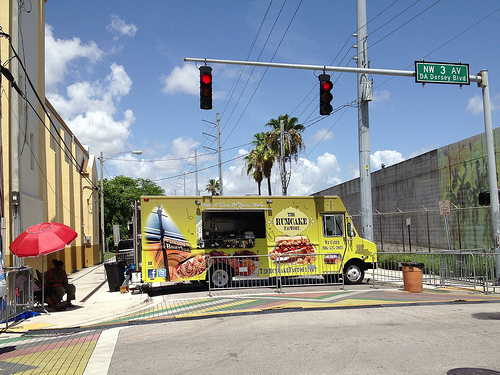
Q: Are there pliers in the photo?
A: No, there are no pliers.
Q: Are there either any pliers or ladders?
A: No, there are no pliers or ladders.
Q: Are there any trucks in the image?
A: Yes, there is a truck.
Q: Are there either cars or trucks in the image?
A: Yes, there is a truck.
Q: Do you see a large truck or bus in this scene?
A: Yes, there is a large truck.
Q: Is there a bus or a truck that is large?
A: Yes, the truck is large.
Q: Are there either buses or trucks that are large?
A: Yes, the truck is large.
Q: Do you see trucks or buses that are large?
A: Yes, the truck is large.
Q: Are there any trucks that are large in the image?
A: Yes, there is a large truck.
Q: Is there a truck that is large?
A: Yes, there is a truck that is large.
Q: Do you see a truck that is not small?
A: Yes, there is a large truck.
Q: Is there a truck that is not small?
A: Yes, there is a large truck.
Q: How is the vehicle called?
A: The vehicle is a truck.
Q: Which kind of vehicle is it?
A: The vehicle is a truck.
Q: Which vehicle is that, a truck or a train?
A: That is a truck.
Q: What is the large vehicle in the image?
A: The vehicle is a truck.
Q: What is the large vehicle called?
A: The vehicle is a truck.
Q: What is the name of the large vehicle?
A: The vehicle is a truck.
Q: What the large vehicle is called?
A: The vehicle is a truck.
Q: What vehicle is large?
A: The vehicle is a truck.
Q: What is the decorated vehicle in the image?
A: The vehicle is a truck.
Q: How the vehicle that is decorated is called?
A: The vehicle is a truck.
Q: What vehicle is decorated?
A: The vehicle is a truck.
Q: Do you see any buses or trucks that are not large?
A: No, there is a truck but it is large.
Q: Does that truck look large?
A: Yes, the truck is large.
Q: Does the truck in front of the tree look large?
A: Yes, the truck is large.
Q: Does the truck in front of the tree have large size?
A: Yes, the truck is large.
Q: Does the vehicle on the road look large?
A: Yes, the truck is large.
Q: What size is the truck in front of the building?
A: The truck is large.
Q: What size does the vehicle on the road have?
A: The truck has large size.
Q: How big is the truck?
A: The truck is large.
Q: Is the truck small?
A: No, the truck is large.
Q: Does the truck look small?
A: No, the truck is large.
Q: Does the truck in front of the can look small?
A: No, the truck is large.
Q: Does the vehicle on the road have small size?
A: No, the truck is large.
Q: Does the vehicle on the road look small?
A: No, the truck is large.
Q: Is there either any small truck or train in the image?
A: No, there is a truck but it is large.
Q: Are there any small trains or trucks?
A: No, there is a truck but it is large.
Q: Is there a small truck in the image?
A: No, there is a truck but it is large.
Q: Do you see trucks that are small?
A: No, there is a truck but it is large.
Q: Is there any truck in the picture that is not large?
A: No, there is a truck but it is large.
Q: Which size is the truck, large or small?
A: The truck is large.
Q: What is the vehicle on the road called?
A: The vehicle is a truck.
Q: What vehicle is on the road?
A: The vehicle is a truck.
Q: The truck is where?
A: The truck is on the road.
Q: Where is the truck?
A: The truck is on the road.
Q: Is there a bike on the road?
A: No, there is a truck on the road.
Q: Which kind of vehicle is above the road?
A: The vehicle is a truck.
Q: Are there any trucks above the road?
A: Yes, there is a truck above the road.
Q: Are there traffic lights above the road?
A: No, there is a truck above the road.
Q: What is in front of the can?
A: The truck is in front of the can.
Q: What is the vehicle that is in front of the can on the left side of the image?
A: The vehicle is a truck.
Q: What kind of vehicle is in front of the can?
A: The vehicle is a truck.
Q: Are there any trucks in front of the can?
A: Yes, there is a truck in front of the can.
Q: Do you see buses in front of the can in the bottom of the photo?
A: No, there is a truck in front of the can.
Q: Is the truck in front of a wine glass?
A: No, the truck is in front of the can.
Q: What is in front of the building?
A: The truck is in front of the building.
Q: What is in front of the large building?
A: The truck is in front of the building.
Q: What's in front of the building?
A: The truck is in front of the building.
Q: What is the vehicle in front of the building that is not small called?
A: The vehicle is a truck.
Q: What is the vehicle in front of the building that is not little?
A: The vehicle is a truck.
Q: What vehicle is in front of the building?
A: The vehicle is a truck.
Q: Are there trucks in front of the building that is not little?
A: Yes, there is a truck in front of the building.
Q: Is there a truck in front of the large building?
A: Yes, there is a truck in front of the building.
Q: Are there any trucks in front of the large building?
A: Yes, there is a truck in front of the building.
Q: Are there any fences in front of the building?
A: No, there is a truck in front of the building.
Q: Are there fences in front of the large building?
A: No, there is a truck in front of the building.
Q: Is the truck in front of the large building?
A: Yes, the truck is in front of the building.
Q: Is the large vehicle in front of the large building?
A: Yes, the truck is in front of the building.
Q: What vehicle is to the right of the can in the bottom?
A: The vehicle is a truck.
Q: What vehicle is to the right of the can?
A: The vehicle is a truck.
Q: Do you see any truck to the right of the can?
A: Yes, there is a truck to the right of the can.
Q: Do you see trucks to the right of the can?
A: Yes, there is a truck to the right of the can.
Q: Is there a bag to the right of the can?
A: No, there is a truck to the right of the can.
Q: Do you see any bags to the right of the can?
A: No, there is a truck to the right of the can.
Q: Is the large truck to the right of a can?
A: Yes, the truck is to the right of a can.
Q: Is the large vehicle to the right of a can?
A: Yes, the truck is to the right of a can.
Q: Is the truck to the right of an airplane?
A: No, the truck is to the right of a can.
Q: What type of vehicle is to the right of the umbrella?
A: The vehicle is a truck.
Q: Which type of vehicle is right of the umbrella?
A: The vehicle is a truck.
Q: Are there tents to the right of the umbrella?
A: No, there is a truck to the right of the umbrella.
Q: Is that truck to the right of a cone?
A: No, the truck is to the right of the umbrella.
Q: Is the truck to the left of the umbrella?
A: No, the truck is to the right of the umbrella.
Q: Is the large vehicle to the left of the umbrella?
A: No, the truck is to the right of the umbrella.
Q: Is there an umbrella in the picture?
A: Yes, there is an umbrella.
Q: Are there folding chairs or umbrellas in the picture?
A: Yes, there is an umbrella.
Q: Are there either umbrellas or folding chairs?
A: Yes, there is an umbrella.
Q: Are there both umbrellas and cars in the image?
A: No, there is an umbrella but no cars.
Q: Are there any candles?
A: No, there are no candles.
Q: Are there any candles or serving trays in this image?
A: No, there are no candles or serving trays.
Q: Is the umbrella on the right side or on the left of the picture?
A: The umbrella is on the left of the image.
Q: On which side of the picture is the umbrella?
A: The umbrella is on the left of the image.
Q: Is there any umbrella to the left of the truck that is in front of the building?
A: Yes, there is an umbrella to the left of the truck.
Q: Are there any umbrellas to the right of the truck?
A: No, the umbrella is to the left of the truck.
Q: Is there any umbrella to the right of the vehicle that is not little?
A: No, the umbrella is to the left of the truck.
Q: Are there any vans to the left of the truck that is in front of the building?
A: No, there is an umbrella to the left of the truck.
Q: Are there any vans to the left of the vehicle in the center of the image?
A: No, there is an umbrella to the left of the truck.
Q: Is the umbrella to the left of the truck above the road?
A: Yes, the umbrella is to the left of the truck.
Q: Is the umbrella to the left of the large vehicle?
A: Yes, the umbrella is to the left of the truck.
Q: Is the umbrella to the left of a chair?
A: No, the umbrella is to the left of the truck.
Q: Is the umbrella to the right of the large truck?
A: No, the umbrella is to the left of the truck.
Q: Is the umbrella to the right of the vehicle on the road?
A: No, the umbrella is to the left of the truck.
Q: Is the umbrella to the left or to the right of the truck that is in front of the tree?
A: The umbrella is to the left of the truck.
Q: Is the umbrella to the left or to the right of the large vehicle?
A: The umbrella is to the left of the truck.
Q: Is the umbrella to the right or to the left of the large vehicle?
A: The umbrella is to the left of the truck.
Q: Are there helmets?
A: No, there are no helmets.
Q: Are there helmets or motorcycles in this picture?
A: No, there are no helmets or motorcycles.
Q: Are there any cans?
A: Yes, there is a can.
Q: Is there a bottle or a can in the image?
A: Yes, there is a can.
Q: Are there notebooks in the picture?
A: No, there are no notebooks.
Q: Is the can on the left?
A: Yes, the can is on the left of the image.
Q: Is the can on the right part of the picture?
A: No, the can is on the left of the image.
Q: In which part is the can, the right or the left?
A: The can is on the left of the image.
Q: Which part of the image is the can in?
A: The can is on the left of the image.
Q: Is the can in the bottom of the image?
A: Yes, the can is in the bottom of the image.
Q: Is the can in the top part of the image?
A: No, the can is in the bottom of the image.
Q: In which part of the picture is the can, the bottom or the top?
A: The can is in the bottom of the image.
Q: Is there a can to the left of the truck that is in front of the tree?
A: Yes, there is a can to the left of the truck.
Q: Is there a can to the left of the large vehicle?
A: Yes, there is a can to the left of the truck.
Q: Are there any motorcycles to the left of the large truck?
A: No, there is a can to the left of the truck.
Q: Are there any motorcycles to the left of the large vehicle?
A: No, there is a can to the left of the truck.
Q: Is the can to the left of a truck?
A: Yes, the can is to the left of a truck.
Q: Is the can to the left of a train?
A: No, the can is to the left of a truck.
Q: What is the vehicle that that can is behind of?
A: The vehicle is a truck.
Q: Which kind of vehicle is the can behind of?
A: The can is behind the truck.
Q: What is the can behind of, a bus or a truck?
A: The can is behind a truck.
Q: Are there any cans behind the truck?
A: Yes, there is a can behind the truck.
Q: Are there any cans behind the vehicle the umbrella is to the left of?
A: Yes, there is a can behind the truck.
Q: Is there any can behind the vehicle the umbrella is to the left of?
A: Yes, there is a can behind the truck.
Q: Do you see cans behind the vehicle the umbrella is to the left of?
A: Yes, there is a can behind the truck.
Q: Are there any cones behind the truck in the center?
A: No, there is a can behind the truck.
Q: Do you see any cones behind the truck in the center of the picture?
A: No, there is a can behind the truck.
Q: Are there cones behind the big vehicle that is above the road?
A: No, there is a can behind the truck.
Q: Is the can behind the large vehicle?
A: Yes, the can is behind the truck.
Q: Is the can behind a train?
A: No, the can is behind the truck.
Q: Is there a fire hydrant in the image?
A: No, there are no fire hydrants.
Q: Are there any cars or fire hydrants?
A: No, there are no fire hydrants or cars.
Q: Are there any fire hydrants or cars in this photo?
A: No, there are no fire hydrants or cars.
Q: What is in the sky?
A: The clouds are in the sky.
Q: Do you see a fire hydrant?
A: No, there are no fire hydrants.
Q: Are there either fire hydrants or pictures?
A: No, there are no fire hydrants or pictures.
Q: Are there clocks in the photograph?
A: No, there are no clocks.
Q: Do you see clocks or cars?
A: No, there are no clocks or cars.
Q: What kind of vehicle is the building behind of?
A: The building is behind the truck.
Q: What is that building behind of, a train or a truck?
A: The building is behind a truck.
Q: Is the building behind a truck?
A: Yes, the building is behind a truck.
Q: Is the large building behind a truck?
A: Yes, the building is behind a truck.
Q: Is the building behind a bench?
A: No, the building is behind a truck.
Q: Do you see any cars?
A: No, there are no cars.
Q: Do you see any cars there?
A: No, there are no cars.